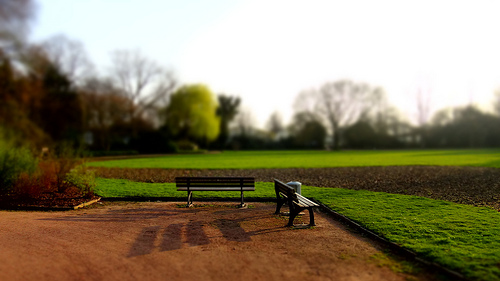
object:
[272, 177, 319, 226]
bench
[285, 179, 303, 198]
trash can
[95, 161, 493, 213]
soil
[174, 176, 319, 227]
benches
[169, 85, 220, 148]
shrub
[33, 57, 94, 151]
tree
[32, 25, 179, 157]
tree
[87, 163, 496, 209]
dirt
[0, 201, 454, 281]
field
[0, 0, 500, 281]
landscape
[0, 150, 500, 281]
field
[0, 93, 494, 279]
park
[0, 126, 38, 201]
trees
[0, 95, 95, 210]
bushes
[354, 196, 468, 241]
grass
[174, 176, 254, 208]
bench